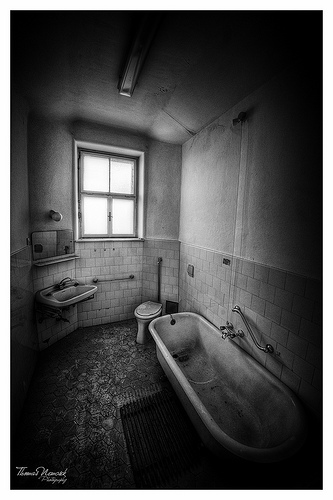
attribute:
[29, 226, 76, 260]
mirror — small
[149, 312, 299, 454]
bathtub — dirty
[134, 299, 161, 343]
toilet — dirty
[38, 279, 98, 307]
sink — dirty